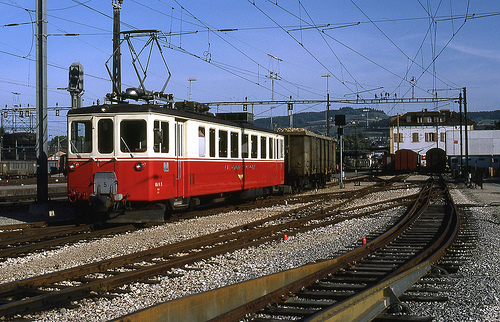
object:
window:
[70, 120, 91, 152]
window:
[97, 116, 116, 154]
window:
[120, 119, 147, 153]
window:
[153, 119, 169, 153]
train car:
[65, 101, 284, 214]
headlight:
[132, 161, 145, 171]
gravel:
[0, 179, 499, 318]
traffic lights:
[63, 64, 86, 98]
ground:
[249, 90, 389, 152]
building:
[390, 109, 500, 176]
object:
[362, 238, 367, 245]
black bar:
[103, 26, 171, 93]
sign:
[334, 113, 347, 126]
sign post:
[338, 135, 344, 190]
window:
[198, 125, 205, 156]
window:
[209, 127, 214, 157]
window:
[218, 129, 229, 158]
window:
[229, 130, 239, 158]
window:
[242, 132, 249, 158]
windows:
[66, 116, 146, 157]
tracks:
[0, 173, 480, 322]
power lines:
[0, 0, 500, 110]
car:
[65, 103, 338, 228]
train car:
[276, 127, 338, 192]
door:
[96, 117, 114, 153]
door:
[173, 116, 185, 196]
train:
[67, 107, 336, 202]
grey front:
[92, 171, 118, 194]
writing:
[225, 164, 256, 171]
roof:
[388, 110, 473, 127]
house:
[385, 108, 500, 181]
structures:
[0, 0, 499, 119]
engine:
[61, 103, 287, 226]